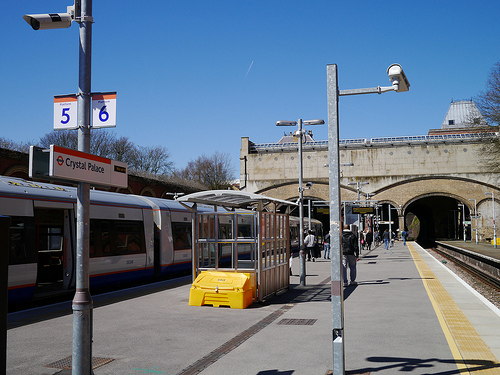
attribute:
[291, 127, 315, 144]
camera — security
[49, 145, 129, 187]
sign — information, white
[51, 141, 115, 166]
stripe — red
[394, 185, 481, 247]
tunnel — arched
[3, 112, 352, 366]
train — blue, white, red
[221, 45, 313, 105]
sky — clear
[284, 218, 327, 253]
car — red, white, blue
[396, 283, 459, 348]
line — long, yellow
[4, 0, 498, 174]
sky — clear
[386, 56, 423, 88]
camera — security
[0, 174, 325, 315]
train car — white, red, blue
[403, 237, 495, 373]
line — thick, yellow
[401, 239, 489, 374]
line — yellow, cement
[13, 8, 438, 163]
sky — clear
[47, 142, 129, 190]
sign — white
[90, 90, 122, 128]
background — white